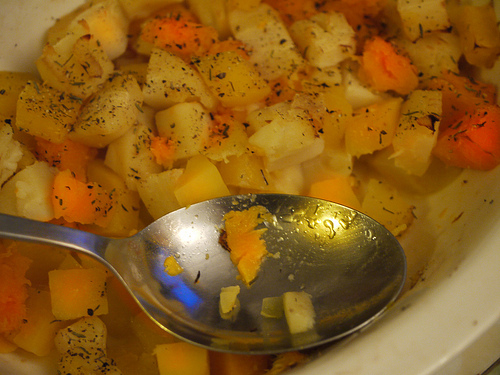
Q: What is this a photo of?
A: Food.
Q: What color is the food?
A: Orange and yellow.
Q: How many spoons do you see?
A: One.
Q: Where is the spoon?
A: In the food.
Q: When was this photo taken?
A: During a meal.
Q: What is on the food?
A: Spices.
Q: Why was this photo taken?
A: To show the food.